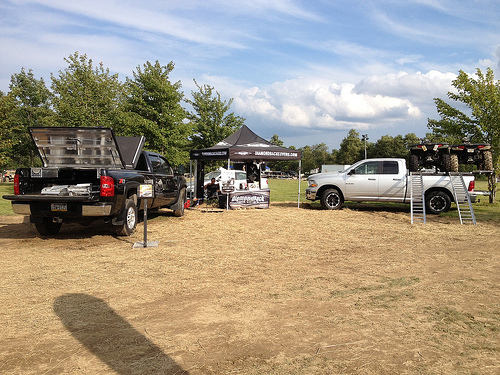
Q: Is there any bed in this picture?
A: Yes, there is a bed.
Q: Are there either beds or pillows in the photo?
A: Yes, there is a bed.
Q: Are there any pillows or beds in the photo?
A: Yes, there is a bed.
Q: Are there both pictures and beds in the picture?
A: No, there is a bed but no pictures.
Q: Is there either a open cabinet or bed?
A: Yes, there is an open bed.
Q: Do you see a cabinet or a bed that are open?
A: Yes, the bed is open.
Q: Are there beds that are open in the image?
A: Yes, there is an open bed.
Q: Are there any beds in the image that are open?
A: Yes, there is a bed that is open.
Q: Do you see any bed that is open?
A: Yes, there is a bed that is open.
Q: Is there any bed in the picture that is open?
A: Yes, there is a bed that is open.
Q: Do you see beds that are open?
A: Yes, there is a bed that is open.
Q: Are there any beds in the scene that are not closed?
A: Yes, there is a open bed.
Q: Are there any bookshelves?
A: No, there are no bookshelves.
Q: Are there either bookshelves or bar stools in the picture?
A: No, there are no bookshelves or bar stools.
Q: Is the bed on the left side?
A: Yes, the bed is on the left of the image.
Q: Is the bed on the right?
A: No, the bed is on the left of the image.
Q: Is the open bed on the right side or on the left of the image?
A: The bed is on the left of the image.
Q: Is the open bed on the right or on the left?
A: The bed is on the left of the image.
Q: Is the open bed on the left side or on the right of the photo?
A: The bed is on the left of the image.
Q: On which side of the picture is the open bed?
A: The bed is on the left of the image.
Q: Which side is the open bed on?
A: The bed is on the left of the image.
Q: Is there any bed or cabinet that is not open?
A: No, there is a bed but it is open.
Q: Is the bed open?
A: Yes, the bed is open.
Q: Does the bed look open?
A: Yes, the bed is open.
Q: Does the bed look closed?
A: No, the bed is open.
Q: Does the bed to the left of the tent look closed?
A: No, the bed is open.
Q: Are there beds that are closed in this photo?
A: No, there is a bed but it is open.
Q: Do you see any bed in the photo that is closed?
A: No, there is a bed but it is open.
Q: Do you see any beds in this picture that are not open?
A: No, there is a bed but it is open.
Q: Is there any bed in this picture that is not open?
A: No, there is a bed but it is open.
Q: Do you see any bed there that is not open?
A: No, there is a bed but it is open.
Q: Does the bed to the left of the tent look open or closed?
A: The bed is open.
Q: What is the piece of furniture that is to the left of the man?
A: The piece of furniture is a bed.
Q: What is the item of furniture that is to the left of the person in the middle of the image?
A: The piece of furniture is a bed.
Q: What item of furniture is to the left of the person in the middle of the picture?
A: The piece of furniture is a bed.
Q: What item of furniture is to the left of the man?
A: The piece of furniture is a bed.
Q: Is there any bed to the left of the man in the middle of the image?
A: Yes, there is a bed to the left of the man.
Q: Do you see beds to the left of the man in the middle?
A: Yes, there is a bed to the left of the man.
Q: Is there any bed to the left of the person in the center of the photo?
A: Yes, there is a bed to the left of the man.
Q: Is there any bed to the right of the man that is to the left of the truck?
A: No, the bed is to the left of the man.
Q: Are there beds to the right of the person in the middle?
A: No, the bed is to the left of the man.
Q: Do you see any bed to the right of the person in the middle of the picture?
A: No, the bed is to the left of the man.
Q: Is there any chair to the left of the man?
A: No, there is a bed to the left of the man.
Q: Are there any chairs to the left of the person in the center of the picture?
A: No, there is a bed to the left of the man.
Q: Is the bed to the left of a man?
A: Yes, the bed is to the left of a man.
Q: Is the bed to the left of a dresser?
A: No, the bed is to the left of a man.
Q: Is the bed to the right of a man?
A: No, the bed is to the left of a man.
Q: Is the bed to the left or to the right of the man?
A: The bed is to the left of the man.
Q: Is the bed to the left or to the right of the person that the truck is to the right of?
A: The bed is to the left of the man.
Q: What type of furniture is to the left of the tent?
A: The piece of furniture is a bed.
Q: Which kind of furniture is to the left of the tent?
A: The piece of furniture is a bed.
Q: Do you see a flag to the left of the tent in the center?
A: No, there is a bed to the left of the tent.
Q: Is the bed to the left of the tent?
A: Yes, the bed is to the left of the tent.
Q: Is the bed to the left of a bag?
A: No, the bed is to the left of the tent.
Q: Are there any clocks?
A: No, there are no clocks.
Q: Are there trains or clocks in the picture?
A: No, there are no clocks or trains.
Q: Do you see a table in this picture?
A: Yes, there is a table.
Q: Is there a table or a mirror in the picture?
A: Yes, there is a table.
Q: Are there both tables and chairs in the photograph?
A: No, there is a table but no chairs.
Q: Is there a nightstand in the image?
A: No, there are no nightstands.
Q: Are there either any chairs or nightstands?
A: No, there are no nightstands or chairs.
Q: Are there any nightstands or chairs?
A: No, there are no nightstands or chairs.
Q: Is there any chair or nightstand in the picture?
A: No, there are no nightstands or chairs.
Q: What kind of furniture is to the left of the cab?
A: The piece of furniture is a table.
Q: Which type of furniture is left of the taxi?
A: The piece of furniture is a table.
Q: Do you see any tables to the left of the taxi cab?
A: Yes, there is a table to the left of the taxi cab.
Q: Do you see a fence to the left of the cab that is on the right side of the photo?
A: No, there is a table to the left of the cab.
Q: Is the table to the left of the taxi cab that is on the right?
A: Yes, the table is to the left of the taxi cab.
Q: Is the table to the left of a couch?
A: No, the table is to the left of the taxi cab.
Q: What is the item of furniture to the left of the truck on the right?
A: The piece of furniture is a table.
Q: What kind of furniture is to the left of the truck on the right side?
A: The piece of furniture is a table.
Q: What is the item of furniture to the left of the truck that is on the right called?
A: The piece of furniture is a table.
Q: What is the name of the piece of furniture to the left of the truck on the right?
A: The piece of furniture is a table.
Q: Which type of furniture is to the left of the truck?
A: The piece of furniture is a table.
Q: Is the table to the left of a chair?
A: No, the table is to the left of the truck.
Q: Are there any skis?
A: No, there are no skis.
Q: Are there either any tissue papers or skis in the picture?
A: No, there are no skis or tissue papers.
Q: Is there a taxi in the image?
A: Yes, there is a taxi.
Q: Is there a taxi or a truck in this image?
A: Yes, there is a taxi.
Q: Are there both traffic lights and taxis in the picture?
A: No, there is a taxi but no traffic lights.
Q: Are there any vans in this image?
A: No, there are no vans.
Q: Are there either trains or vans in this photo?
A: No, there are no vans or trains.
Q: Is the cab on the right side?
A: Yes, the cab is on the right of the image.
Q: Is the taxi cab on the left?
A: No, the taxi cab is on the right of the image.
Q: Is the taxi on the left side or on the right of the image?
A: The taxi is on the right of the image.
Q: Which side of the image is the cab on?
A: The cab is on the right of the image.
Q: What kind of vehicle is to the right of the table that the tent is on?
A: The vehicle is a taxi.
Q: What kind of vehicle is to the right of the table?
A: The vehicle is a taxi.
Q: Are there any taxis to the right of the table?
A: Yes, there is a taxi to the right of the table.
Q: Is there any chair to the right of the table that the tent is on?
A: No, there is a taxi to the right of the table.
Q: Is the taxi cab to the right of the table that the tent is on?
A: Yes, the taxi cab is to the right of the table.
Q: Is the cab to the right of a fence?
A: No, the cab is to the right of the table.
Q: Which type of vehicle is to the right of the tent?
A: The vehicle is a taxi.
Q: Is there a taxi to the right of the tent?
A: Yes, there is a taxi to the right of the tent.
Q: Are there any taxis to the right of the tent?
A: Yes, there is a taxi to the right of the tent.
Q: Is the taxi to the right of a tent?
A: Yes, the taxi is to the right of a tent.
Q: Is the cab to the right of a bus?
A: No, the cab is to the right of a tent.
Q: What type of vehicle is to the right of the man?
A: The vehicle is a taxi.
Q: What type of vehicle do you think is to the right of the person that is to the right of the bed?
A: The vehicle is a taxi.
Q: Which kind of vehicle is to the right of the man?
A: The vehicle is a taxi.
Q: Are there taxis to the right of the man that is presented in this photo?
A: Yes, there is a taxi to the right of the man.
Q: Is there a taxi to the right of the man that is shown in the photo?
A: Yes, there is a taxi to the right of the man.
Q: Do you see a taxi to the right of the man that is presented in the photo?
A: Yes, there is a taxi to the right of the man.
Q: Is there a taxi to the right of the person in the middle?
A: Yes, there is a taxi to the right of the man.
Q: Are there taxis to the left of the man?
A: No, the taxi is to the right of the man.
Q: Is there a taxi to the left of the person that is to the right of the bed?
A: No, the taxi is to the right of the man.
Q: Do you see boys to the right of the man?
A: No, there is a taxi to the right of the man.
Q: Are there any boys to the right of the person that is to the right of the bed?
A: No, there is a taxi to the right of the man.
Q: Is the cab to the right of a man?
A: Yes, the cab is to the right of a man.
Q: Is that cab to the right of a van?
A: No, the cab is to the right of a man.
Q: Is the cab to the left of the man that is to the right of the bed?
A: No, the cab is to the right of the man.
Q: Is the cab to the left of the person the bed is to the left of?
A: No, the cab is to the right of the man.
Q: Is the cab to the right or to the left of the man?
A: The cab is to the right of the man.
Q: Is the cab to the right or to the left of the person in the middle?
A: The cab is to the right of the man.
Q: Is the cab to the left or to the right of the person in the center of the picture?
A: The cab is to the right of the man.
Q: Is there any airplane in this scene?
A: No, there are no airplanes.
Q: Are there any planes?
A: No, there are no planes.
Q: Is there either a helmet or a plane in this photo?
A: No, there are no airplanes or helmets.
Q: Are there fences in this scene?
A: No, there are no fences.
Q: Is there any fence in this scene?
A: No, there are no fences.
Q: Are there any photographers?
A: No, there are no photographers.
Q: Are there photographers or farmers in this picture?
A: No, there are no photographers or farmers.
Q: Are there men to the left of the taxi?
A: Yes, there is a man to the left of the taxi.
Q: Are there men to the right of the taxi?
A: No, the man is to the left of the taxi.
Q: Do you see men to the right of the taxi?
A: No, the man is to the left of the taxi.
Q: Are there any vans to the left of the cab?
A: No, there is a man to the left of the cab.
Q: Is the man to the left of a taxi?
A: Yes, the man is to the left of a taxi.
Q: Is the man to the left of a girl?
A: No, the man is to the left of a taxi.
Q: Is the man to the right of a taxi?
A: No, the man is to the left of a taxi.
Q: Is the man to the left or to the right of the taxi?
A: The man is to the left of the taxi.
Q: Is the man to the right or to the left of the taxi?
A: The man is to the left of the taxi.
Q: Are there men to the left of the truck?
A: Yes, there is a man to the left of the truck.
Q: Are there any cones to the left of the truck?
A: No, there is a man to the left of the truck.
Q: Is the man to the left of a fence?
A: No, the man is to the left of the truck.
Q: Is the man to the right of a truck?
A: No, the man is to the left of a truck.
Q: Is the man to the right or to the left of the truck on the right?
A: The man is to the left of the truck.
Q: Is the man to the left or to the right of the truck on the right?
A: The man is to the left of the truck.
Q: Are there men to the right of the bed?
A: Yes, there is a man to the right of the bed.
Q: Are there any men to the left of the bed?
A: No, the man is to the right of the bed.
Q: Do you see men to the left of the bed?
A: No, the man is to the right of the bed.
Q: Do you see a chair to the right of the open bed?
A: No, there is a man to the right of the bed.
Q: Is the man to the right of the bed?
A: Yes, the man is to the right of the bed.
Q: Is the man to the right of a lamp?
A: No, the man is to the right of the bed.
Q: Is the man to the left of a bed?
A: No, the man is to the right of a bed.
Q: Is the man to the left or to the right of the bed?
A: The man is to the right of the bed.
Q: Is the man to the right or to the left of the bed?
A: The man is to the right of the bed.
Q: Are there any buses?
A: No, there are no buses.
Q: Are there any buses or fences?
A: No, there are no buses or fences.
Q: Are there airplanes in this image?
A: No, there are no airplanes.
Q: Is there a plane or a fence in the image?
A: No, there are no airplanes or fences.